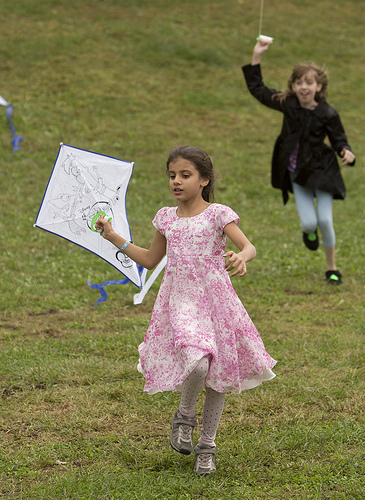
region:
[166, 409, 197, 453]
a girl's gray tennis shoe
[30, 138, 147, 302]
a blue and white kite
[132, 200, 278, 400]
a girl's pink and white dress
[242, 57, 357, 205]
a girl's black top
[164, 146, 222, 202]
part of a girl's long hair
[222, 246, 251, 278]
the hand of a girl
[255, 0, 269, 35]
a white kite string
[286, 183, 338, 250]
a girl's blue leggings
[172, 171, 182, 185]
the nose of a girl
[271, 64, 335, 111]
a girl's long brown hair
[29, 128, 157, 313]
A white kite with cartoon characters on it.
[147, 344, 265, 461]
Polka-dot tights and tennis shoes.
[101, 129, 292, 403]
A young girl wearing a pink dress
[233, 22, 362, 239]
A young girl wearing jeans and a black coat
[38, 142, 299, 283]
A girl holding a kite.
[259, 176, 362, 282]
Blue leggings and black tennis shoes with green laces.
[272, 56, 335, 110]
A young girl smiling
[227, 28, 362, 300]
A girl running on the grass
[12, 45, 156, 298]
A white kite in front of grass.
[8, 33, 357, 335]
Two girls running in a field.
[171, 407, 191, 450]
gray and white shoe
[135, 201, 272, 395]
a pink and white dress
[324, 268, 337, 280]
green abd black shoe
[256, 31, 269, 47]
a string holder in her hand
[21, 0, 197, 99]
a green grassy field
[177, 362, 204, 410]
polks dotted socks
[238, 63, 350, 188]
a black coat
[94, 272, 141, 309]
a blue tail on the kite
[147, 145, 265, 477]
a girl in a pink and white dress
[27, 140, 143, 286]
White and blue diamond shaped kite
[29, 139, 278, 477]
A young girl running with a kite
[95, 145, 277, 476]
Little girl wearing all pink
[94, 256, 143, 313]
Blue streamer tailing a kite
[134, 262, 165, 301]
A white streamer behind a kite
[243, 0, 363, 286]
A girl running with a kite flying outside the shot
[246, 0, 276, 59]
A hand holding a kite string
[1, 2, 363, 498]
A grassy field and hill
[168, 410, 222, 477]
Pink and grey tennis shoes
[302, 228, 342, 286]
Green and black shoes running on grass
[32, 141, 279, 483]
girl in a pink dress with a kite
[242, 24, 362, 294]
a girl running in a yard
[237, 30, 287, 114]
the arm of a child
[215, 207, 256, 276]
the arm of a girl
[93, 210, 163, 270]
the arm of a girl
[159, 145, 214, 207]
the head of a girl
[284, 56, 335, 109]
the head of a child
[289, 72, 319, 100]
the face of a child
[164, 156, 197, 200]
the face of a girl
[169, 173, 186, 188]
the nose of a girl